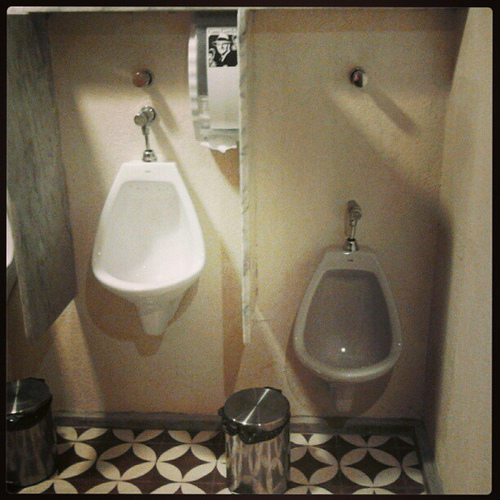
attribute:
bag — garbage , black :
[11, 392, 51, 435]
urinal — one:
[286, 234, 420, 460]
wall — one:
[33, 13, 263, 414]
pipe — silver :
[336, 199, 368, 249]